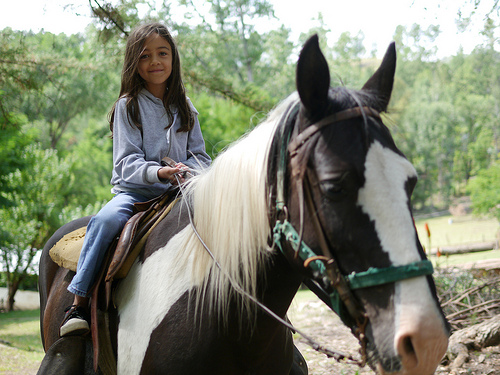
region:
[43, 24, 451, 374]
young girl on horse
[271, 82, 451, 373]
horse has green bridle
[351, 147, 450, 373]
horse has white stripe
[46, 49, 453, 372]
horse is dark brown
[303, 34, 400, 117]
horse has two ears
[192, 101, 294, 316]
horse has blonde hair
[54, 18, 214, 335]
girl wearing black shoes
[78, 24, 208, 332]
girl wearing blue pants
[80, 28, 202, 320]
girl wearing gray shirt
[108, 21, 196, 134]
girl has long hair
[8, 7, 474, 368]
A girl riding a brown and white horse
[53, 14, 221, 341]
A child with long dark hair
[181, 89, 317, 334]
A horse's white mane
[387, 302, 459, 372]
A horse's white nose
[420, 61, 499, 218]
Trees growing in the background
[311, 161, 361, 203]
A horse's right eye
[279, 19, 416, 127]
A horse's two ears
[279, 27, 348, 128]
A horse's right ear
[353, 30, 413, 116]
A horse's left ear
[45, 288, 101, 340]
A child's shoe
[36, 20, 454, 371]
a girl sitting on a horse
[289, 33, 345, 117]
the ear of a horse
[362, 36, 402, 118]
the ear of a horse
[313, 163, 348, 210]
the eye of a horse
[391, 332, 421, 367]
a nostril of a horse's nose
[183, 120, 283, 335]
the mane of a horse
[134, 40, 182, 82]
a face of a girl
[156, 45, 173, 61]
the eye of a girl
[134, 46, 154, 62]
the eye of a girl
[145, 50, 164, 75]
the nose of a girl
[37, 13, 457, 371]
girl is riding a horse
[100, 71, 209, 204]
the jacket is gray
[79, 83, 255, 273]
the jacket is gray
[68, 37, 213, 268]
girl sits on horse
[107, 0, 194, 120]
girl has brown hair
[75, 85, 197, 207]
girl has grey shirt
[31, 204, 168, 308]
girl has blue jeans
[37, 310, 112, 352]
black and white shoes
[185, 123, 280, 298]
horse has blond mane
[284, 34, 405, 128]
horse has brown ears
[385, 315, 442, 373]
horse has pink nose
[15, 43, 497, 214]
green trees behind horse